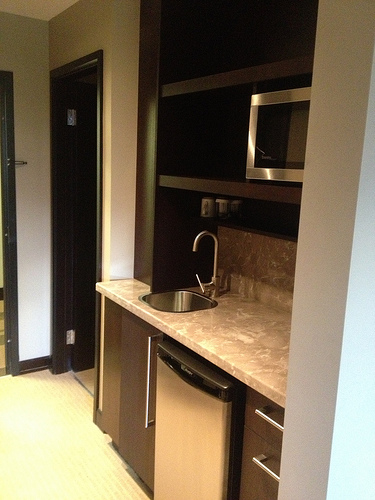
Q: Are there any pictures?
A: No, there are no pictures.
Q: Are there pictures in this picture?
A: No, there are no pictures.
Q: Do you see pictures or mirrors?
A: No, there are no pictures or mirrors.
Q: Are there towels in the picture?
A: No, there are no towels.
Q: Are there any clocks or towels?
A: No, there are no towels or clocks.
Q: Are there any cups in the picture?
A: Yes, there is a cup.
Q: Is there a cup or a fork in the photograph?
A: Yes, there is a cup.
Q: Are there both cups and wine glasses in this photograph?
A: No, there is a cup but no wine glasses.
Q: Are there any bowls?
A: No, there are no bowls.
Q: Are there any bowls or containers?
A: No, there are no bowls or containers.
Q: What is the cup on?
A: The cup is on the shelf.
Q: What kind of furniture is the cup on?
A: The cup is on the shelf.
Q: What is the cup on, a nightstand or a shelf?
A: The cup is on a shelf.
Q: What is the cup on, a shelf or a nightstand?
A: The cup is on a shelf.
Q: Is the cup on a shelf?
A: Yes, the cup is on a shelf.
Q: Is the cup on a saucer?
A: No, the cup is on a shelf.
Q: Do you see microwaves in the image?
A: Yes, there is a microwave.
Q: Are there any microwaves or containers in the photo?
A: Yes, there is a microwave.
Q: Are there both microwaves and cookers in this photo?
A: No, there is a microwave but no cookers.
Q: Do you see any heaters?
A: No, there are no heaters.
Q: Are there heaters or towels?
A: No, there are no heaters or towels.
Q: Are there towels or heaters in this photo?
A: No, there are no heaters or towels.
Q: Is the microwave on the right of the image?
A: Yes, the microwave is on the right of the image.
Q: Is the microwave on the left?
A: No, the microwave is on the right of the image.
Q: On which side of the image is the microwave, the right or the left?
A: The microwave is on the right of the image.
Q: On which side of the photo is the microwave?
A: The microwave is on the right of the image.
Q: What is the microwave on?
A: The microwave is on the shelf.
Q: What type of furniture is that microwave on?
A: The microwave is on the shelf.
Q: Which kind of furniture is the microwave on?
A: The microwave is on the shelf.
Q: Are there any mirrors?
A: No, there are no mirrors.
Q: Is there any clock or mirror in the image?
A: No, there are no mirrors or clocks.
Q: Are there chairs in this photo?
A: No, there are no chairs.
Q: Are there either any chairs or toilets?
A: No, there are no chairs or toilets.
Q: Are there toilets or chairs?
A: No, there are no chairs or toilets.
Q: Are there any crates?
A: No, there are no crates.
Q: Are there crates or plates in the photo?
A: No, there are no crates or plates.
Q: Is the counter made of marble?
A: Yes, the counter is made of marble.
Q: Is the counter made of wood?
A: No, the counter is made of marble.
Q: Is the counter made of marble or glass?
A: The counter is made of marble.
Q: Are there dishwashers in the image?
A: Yes, there is a dishwasher.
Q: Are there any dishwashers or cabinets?
A: Yes, there is a dishwasher.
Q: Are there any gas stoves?
A: No, there are no gas stoves.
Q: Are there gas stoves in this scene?
A: No, there are no gas stoves.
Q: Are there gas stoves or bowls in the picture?
A: No, there are no gas stoves or bowls.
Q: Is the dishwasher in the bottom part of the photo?
A: Yes, the dishwasher is in the bottom of the image.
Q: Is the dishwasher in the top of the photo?
A: No, the dishwasher is in the bottom of the image.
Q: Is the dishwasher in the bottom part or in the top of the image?
A: The dishwasher is in the bottom of the image.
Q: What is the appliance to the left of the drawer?
A: The appliance is a dishwasher.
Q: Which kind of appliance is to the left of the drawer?
A: The appliance is a dishwasher.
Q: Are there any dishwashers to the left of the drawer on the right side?
A: Yes, there is a dishwasher to the left of the drawer.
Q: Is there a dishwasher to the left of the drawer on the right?
A: Yes, there is a dishwasher to the left of the drawer.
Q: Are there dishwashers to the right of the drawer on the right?
A: No, the dishwasher is to the left of the drawer.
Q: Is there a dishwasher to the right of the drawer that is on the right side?
A: No, the dishwasher is to the left of the drawer.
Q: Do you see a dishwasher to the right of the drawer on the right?
A: No, the dishwasher is to the left of the drawer.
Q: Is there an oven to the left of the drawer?
A: No, there is a dishwasher to the left of the drawer.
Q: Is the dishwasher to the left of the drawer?
A: Yes, the dishwasher is to the left of the drawer.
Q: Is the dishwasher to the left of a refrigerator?
A: No, the dishwasher is to the left of the drawer.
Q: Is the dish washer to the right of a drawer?
A: No, the dish washer is to the left of a drawer.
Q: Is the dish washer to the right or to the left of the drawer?
A: The dish washer is to the left of the drawer.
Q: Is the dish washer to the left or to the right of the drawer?
A: The dish washer is to the left of the drawer.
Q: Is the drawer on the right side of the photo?
A: Yes, the drawer is on the right of the image.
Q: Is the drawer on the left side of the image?
A: No, the drawer is on the right of the image.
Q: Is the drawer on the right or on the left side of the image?
A: The drawer is on the right of the image.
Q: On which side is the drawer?
A: The drawer is on the right of the image.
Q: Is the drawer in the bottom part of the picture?
A: Yes, the drawer is in the bottom of the image.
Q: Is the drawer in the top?
A: No, the drawer is in the bottom of the image.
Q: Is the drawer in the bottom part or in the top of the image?
A: The drawer is in the bottom of the image.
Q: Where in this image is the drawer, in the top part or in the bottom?
A: The drawer is in the bottom of the image.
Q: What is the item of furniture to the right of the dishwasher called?
A: The piece of furniture is a drawer.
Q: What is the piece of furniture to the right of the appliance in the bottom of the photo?
A: The piece of furniture is a drawer.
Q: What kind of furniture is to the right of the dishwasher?
A: The piece of furniture is a drawer.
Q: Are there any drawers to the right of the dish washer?
A: Yes, there is a drawer to the right of the dish washer.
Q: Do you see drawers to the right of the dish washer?
A: Yes, there is a drawer to the right of the dish washer.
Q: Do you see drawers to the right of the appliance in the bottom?
A: Yes, there is a drawer to the right of the dish washer.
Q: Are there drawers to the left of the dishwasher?
A: No, the drawer is to the right of the dishwasher.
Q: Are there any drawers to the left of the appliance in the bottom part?
A: No, the drawer is to the right of the dishwasher.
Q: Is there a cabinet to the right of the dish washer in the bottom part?
A: No, there is a drawer to the right of the dishwasher.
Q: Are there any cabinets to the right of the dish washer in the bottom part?
A: No, there is a drawer to the right of the dishwasher.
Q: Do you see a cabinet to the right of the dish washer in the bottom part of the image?
A: No, there is a drawer to the right of the dishwasher.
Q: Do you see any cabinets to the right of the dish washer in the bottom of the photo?
A: No, there is a drawer to the right of the dishwasher.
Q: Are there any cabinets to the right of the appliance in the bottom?
A: No, there is a drawer to the right of the dishwasher.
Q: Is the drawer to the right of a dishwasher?
A: Yes, the drawer is to the right of a dishwasher.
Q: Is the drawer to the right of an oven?
A: No, the drawer is to the right of a dishwasher.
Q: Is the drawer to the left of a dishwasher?
A: No, the drawer is to the right of a dishwasher.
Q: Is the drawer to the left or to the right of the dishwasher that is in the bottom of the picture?
A: The drawer is to the right of the dishwasher.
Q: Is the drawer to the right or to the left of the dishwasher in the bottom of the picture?
A: The drawer is to the right of the dishwasher.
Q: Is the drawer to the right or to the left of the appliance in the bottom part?
A: The drawer is to the right of the dishwasher.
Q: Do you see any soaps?
A: No, there are no soaps.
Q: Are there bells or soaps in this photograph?
A: No, there are no soaps or bells.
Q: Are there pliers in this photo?
A: No, there are no pliers.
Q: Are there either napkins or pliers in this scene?
A: No, there are no pliers or napkins.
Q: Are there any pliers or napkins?
A: No, there are no pliers or napkins.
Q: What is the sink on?
A: The sink is on the counter.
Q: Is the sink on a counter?
A: Yes, the sink is on a counter.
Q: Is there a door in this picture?
A: Yes, there is a door.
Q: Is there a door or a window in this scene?
A: Yes, there is a door.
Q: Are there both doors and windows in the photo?
A: No, there is a door but no windows.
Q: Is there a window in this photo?
A: No, there are no windows.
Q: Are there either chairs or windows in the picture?
A: No, there are no windows or chairs.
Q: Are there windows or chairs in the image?
A: No, there are no windows or chairs.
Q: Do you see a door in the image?
A: Yes, there is a door.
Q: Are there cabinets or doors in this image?
A: Yes, there is a door.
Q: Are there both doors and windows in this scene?
A: No, there is a door but no windows.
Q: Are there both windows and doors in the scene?
A: No, there is a door but no windows.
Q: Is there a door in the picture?
A: Yes, there is a door.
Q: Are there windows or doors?
A: Yes, there is a door.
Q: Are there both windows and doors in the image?
A: No, there is a door but no windows.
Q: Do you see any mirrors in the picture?
A: No, there are no mirrors.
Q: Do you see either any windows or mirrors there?
A: No, there are no mirrors or windows.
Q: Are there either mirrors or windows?
A: No, there are no mirrors or windows.